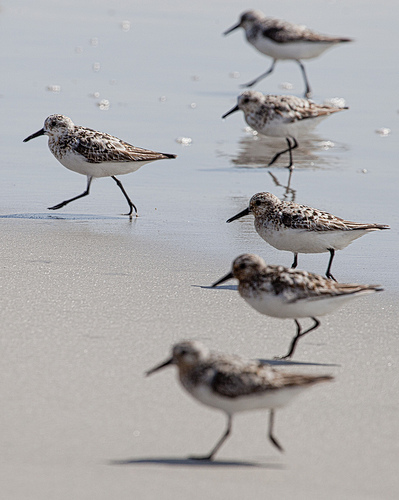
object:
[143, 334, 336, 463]
bird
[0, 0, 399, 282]
sea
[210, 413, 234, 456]
leg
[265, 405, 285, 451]
leg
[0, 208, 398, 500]
sand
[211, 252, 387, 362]
bird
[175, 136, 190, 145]
bubble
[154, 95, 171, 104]
bubble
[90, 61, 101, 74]
bubble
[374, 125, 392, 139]
bubble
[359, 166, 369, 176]
bubble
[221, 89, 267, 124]
head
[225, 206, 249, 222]
beak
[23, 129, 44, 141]
beak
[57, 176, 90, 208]
leg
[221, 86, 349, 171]
bird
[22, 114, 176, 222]
bird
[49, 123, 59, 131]
eye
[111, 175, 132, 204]
leg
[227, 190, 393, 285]
bird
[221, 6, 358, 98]
bird